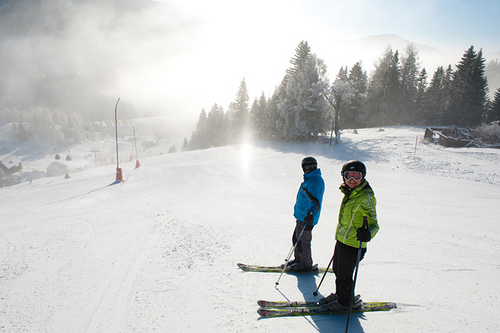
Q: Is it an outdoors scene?
A: Yes, it is outdoors.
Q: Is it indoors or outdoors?
A: It is outdoors.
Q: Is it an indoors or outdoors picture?
A: It is outdoors.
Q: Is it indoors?
A: No, it is outdoors.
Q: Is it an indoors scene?
A: No, it is outdoors.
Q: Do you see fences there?
A: No, there are no fences.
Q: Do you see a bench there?
A: No, there are no benches.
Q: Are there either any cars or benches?
A: No, there are no benches or cars.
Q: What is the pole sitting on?
A: The pole is sitting on the mountain.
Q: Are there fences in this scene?
A: No, there are no fences.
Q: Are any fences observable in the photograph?
A: No, there are no fences.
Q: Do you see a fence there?
A: No, there are no fences.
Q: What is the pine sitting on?
A: The pine is sitting on the mountain.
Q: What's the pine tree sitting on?
A: The pine is sitting on the mountain.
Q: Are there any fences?
A: No, there are no fences.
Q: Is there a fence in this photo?
A: No, there are no fences.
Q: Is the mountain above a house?
A: Yes, the mountain is above a house.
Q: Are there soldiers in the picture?
A: No, there are no soldiers.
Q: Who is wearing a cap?
A: The skier is wearing a cap.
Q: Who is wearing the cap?
A: The skier is wearing a cap.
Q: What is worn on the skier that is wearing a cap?
A: The jacket is worn on the skier.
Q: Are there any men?
A: No, there are no men.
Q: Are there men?
A: No, there are no men.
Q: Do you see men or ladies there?
A: No, there are no men or ladies.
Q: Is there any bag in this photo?
A: No, there are no bags.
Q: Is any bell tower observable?
A: No, there are no bell towers.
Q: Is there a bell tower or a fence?
A: No, there are no bell towers or fences.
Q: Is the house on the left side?
A: Yes, the house is on the left of the image.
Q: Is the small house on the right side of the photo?
A: No, the house is on the left of the image.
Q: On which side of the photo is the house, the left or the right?
A: The house is on the left of the image.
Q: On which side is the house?
A: The house is on the left of the image.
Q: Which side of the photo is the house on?
A: The house is on the left of the image.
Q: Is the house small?
A: Yes, the house is small.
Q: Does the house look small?
A: Yes, the house is small.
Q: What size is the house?
A: The house is small.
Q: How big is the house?
A: The house is small.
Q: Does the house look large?
A: No, the house is small.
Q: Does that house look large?
A: No, the house is small.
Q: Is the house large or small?
A: The house is small.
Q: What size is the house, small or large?
A: The house is small.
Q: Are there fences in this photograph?
A: No, there are no fences.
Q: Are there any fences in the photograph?
A: No, there are no fences.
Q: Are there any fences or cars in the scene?
A: No, there are no fences or cars.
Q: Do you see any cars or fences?
A: No, there are no fences or cars.